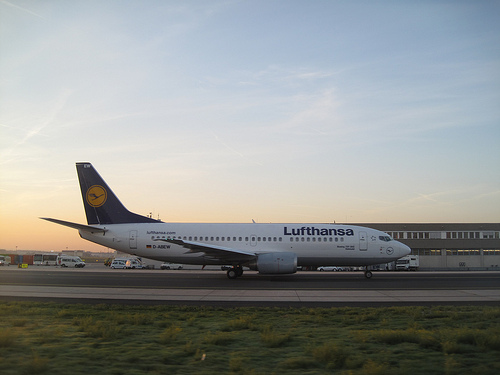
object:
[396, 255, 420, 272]
truck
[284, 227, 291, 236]
letters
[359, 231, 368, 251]
door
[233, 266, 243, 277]
wheel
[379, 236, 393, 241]
windshield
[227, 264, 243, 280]
landing gear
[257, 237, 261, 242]
window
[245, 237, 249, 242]
window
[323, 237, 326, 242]
window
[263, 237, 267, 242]
window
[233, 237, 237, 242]
window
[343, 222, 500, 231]
roof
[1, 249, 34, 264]
building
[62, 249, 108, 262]
building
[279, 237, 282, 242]
window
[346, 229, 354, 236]
writing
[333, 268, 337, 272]
wheel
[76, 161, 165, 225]
blue tail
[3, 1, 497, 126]
sky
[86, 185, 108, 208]
orange symbol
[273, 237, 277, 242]
window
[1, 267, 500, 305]
airport runway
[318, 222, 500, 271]
building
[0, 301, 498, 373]
grass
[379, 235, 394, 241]
window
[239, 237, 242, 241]
window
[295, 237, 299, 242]
windows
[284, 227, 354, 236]
logo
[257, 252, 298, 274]
engine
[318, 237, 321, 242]
window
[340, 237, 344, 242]
passenger window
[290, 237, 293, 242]
passenger window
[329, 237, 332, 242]
passenger window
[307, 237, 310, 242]
passenger window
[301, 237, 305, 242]
passenger window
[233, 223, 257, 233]
white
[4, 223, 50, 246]
sunset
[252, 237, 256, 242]
window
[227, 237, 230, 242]
window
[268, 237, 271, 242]
window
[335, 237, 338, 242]
window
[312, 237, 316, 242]
window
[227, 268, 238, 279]
wheel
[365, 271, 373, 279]
gear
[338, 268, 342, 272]
wheel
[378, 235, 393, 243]
cockpit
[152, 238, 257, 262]
wing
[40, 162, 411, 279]
airplane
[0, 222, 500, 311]
airport